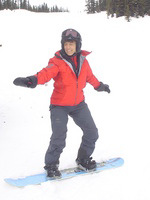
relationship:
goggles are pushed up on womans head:
[54, 26, 78, 40] [56, 28, 92, 60]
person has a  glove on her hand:
[13, 26, 110, 181] [91, 80, 114, 95]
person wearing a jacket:
[13, 26, 110, 181] [49, 55, 87, 102]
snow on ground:
[97, 28, 129, 68] [66, 154, 149, 200]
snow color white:
[92, 61, 149, 143] [99, 194, 147, 200]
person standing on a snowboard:
[13, 26, 110, 181] [16, 148, 116, 176]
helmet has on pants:
[61, 28, 82, 49] [46, 53, 93, 101]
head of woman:
[51, 20, 91, 62] [43, 29, 93, 73]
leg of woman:
[75, 105, 101, 169] [45, 78, 106, 167]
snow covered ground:
[95, 121, 147, 154] [109, 155, 149, 169]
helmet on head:
[60, 30, 88, 49] [52, 26, 87, 66]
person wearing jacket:
[9, 26, 110, 181] [26, 48, 99, 104]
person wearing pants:
[13, 26, 110, 181] [43, 100, 98, 169]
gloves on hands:
[11, 70, 114, 97] [9, 67, 114, 101]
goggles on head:
[62, 29, 78, 38] [61, 28, 82, 56]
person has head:
[9, 26, 110, 181] [61, 28, 82, 56]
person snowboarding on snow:
[13, 26, 110, 181] [100, 27, 149, 63]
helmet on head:
[61, 28, 82, 49] [62, 40, 76, 56]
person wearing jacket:
[13, 26, 110, 181] [35, 58, 92, 101]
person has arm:
[13, 26, 110, 181] [84, 58, 109, 93]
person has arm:
[13, 26, 110, 181] [10, 56, 64, 87]